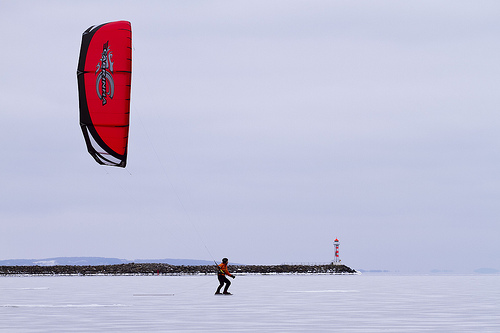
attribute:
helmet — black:
[212, 256, 240, 287]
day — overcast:
[2, 5, 497, 331]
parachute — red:
[71, 12, 147, 174]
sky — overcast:
[154, 102, 396, 204]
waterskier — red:
[213, 256, 235, 294]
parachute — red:
[76, 12, 131, 172]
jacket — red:
[213, 258, 235, 283]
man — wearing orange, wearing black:
[208, 255, 235, 296]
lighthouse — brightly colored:
[328, 234, 345, 269]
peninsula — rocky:
[0, 260, 359, 277]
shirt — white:
[325, 231, 347, 268]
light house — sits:
[330, 231, 342, 259]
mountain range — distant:
[2, 259, 219, 280]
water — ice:
[13, 295, 131, 320]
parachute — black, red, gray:
[77, 20, 130, 166]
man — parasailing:
[215, 260, 235, 294]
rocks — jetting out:
[2, 263, 355, 274]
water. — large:
[275, 268, 440, 330]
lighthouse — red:
[330, 234, 341, 272]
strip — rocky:
[3, 254, 356, 281]